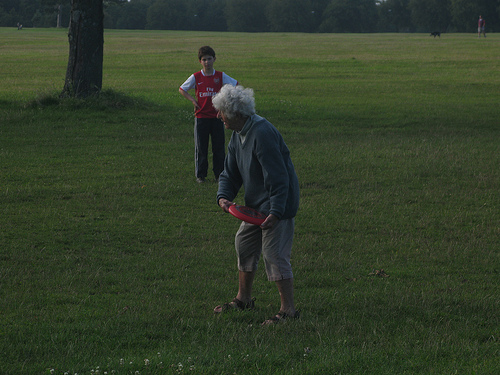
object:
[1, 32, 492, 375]
ground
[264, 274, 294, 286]
edge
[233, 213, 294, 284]
short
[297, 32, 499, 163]
grass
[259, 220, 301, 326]
leg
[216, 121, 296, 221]
gray sweater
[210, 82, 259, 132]
head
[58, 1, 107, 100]
tree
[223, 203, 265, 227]
frisbee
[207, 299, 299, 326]
sandals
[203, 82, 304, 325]
man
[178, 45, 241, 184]
boy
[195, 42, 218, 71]
head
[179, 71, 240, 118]
jersey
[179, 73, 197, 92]
sleeve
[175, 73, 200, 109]
arm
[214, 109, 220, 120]
nose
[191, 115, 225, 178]
pants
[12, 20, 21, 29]
dog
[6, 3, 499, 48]
background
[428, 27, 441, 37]
dog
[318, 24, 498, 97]
field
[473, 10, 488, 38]
person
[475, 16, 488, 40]
owner